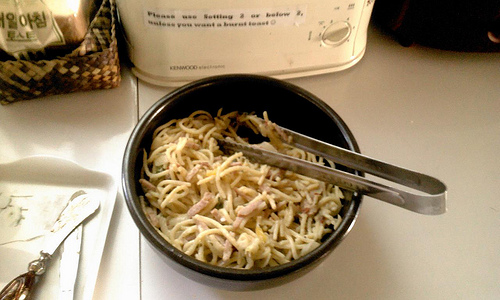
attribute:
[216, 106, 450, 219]
tongs — silver, metal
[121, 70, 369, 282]
bowl — with edge, black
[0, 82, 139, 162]
shade — existing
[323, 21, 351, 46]
handle — existing, white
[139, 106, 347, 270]
pasta — white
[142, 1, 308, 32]
sign — white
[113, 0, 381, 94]
toaster — white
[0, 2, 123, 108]
basket — woven